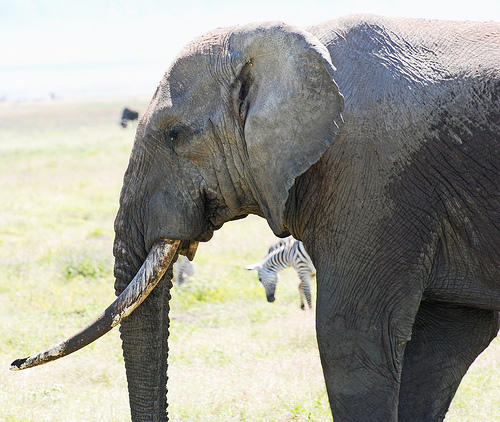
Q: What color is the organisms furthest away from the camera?
A: Black.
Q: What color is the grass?
A: Green.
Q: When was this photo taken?
A: Day time.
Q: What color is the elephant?
A: Gray.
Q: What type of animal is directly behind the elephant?
A: Zebra.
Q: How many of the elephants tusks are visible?
A: One.